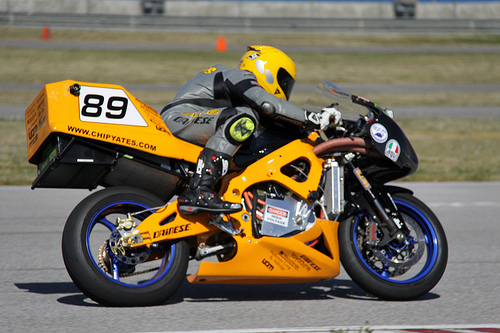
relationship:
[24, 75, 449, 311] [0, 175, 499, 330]
bike on highway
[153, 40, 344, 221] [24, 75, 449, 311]
man riding bike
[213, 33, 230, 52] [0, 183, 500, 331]
cone background of racing track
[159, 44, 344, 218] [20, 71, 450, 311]
man on bike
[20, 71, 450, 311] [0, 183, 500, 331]
bike on racing track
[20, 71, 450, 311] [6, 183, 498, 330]
bike rides on surface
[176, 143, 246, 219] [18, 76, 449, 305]
boot on person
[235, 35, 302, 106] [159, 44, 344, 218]
helmet on man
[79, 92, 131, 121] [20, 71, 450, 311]
number on bike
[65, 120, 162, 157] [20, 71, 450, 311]
info on bike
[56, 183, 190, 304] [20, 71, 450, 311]
motorcycle tires on bike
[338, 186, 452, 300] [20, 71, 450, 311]
motorcycle wheel/rims on bike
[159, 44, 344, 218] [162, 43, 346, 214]
man being driven by man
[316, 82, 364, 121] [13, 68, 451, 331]
glass windshield of motorcycle